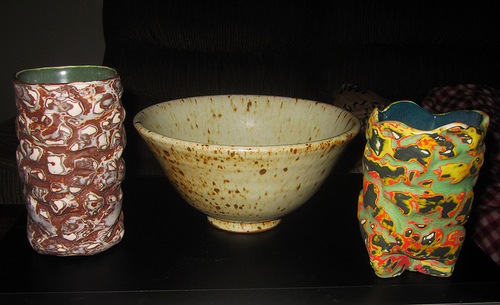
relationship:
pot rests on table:
[357, 100, 490, 275] [19, 183, 496, 299]